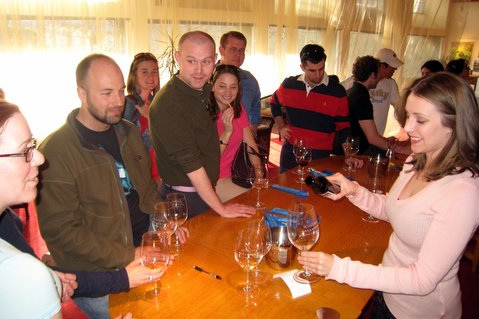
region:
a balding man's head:
[71, 52, 129, 123]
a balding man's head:
[167, 29, 213, 83]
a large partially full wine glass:
[140, 229, 175, 302]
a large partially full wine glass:
[151, 200, 177, 248]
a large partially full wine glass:
[165, 190, 191, 252]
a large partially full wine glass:
[232, 225, 265, 300]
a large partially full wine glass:
[249, 214, 270, 261]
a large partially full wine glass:
[288, 200, 322, 286]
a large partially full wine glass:
[251, 162, 270, 211]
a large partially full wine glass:
[292, 134, 308, 169]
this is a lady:
[342, 71, 478, 310]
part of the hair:
[457, 105, 474, 136]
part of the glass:
[242, 239, 259, 256]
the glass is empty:
[230, 219, 261, 301]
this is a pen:
[187, 255, 226, 283]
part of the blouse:
[425, 210, 446, 244]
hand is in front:
[208, 192, 247, 218]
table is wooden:
[191, 280, 225, 315]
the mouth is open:
[407, 132, 425, 142]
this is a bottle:
[304, 171, 324, 192]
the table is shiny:
[184, 260, 246, 302]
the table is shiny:
[193, 247, 266, 314]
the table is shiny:
[238, 280, 261, 303]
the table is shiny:
[173, 265, 201, 288]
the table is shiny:
[200, 295, 223, 312]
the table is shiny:
[204, 291, 235, 315]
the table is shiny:
[205, 288, 281, 315]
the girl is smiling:
[181, 52, 261, 128]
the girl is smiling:
[210, 27, 282, 216]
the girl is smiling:
[210, 57, 252, 144]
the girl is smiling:
[204, 63, 316, 279]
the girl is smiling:
[191, 70, 302, 179]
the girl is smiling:
[196, 75, 278, 143]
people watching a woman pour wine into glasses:
[18, 41, 453, 243]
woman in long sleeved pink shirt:
[328, 75, 473, 306]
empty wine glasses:
[135, 160, 314, 294]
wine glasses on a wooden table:
[179, 208, 382, 306]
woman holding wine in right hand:
[291, 156, 374, 229]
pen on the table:
[192, 256, 232, 284]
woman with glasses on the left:
[0, 73, 60, 228]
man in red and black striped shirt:
[274, 30, 366, 174]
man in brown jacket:
[53, 49, 159, 258]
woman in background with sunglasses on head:
[111, 33, 177, 113]